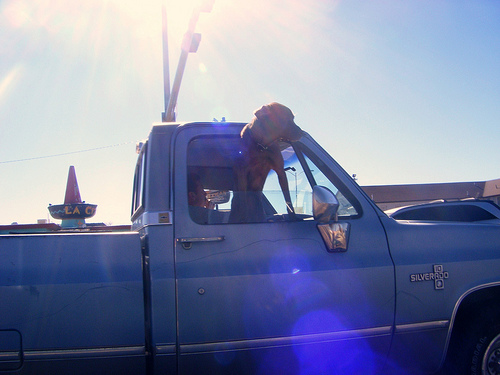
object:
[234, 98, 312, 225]
dog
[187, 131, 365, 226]
window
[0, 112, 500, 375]
truck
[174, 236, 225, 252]
handle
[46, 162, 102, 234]
sign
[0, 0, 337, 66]
sun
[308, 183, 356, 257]
mirror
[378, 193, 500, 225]
vehicle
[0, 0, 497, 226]
sky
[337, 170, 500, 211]
building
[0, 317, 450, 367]
stripe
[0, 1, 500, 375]
photo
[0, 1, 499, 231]
distance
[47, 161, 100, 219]
hat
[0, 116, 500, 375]
side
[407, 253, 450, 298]
logo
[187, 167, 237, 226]
driver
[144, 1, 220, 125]
pole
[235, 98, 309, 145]
head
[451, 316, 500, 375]
wheel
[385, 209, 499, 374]
front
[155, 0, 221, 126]
signal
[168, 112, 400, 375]
door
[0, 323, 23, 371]
tank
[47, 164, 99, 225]
sombrero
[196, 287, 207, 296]
keyhole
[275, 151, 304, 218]
leg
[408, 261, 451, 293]
plate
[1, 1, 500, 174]
sunshine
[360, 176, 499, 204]
roof